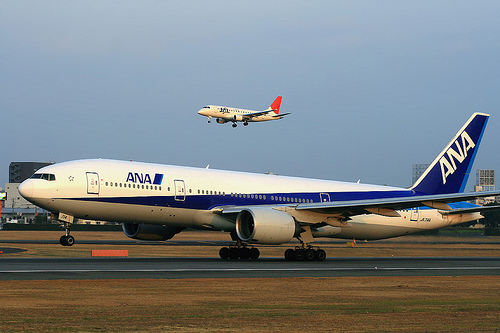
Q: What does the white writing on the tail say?
A: ANA.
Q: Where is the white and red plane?
A: In the sky.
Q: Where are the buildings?
A: Behind the planes.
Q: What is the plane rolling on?
A: Landing gear.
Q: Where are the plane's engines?
A: On its wings.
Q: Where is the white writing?
A: Plane's tail.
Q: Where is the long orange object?
A: Beside the runway.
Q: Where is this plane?
A: On the runway.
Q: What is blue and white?
A: A plane.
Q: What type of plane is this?
A: A passenger plane.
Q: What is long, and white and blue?
A: A plane.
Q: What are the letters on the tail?
A: ANA.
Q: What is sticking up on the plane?
A: A tail.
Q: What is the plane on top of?
A: A runway.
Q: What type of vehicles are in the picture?
A: Airplanes.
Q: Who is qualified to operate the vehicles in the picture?
A: An airplane pilot.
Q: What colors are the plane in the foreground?
A: Blue and white.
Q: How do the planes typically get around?
A: By flying.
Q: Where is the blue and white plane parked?
A: On the Tarmac.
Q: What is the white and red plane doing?
A: Flying.